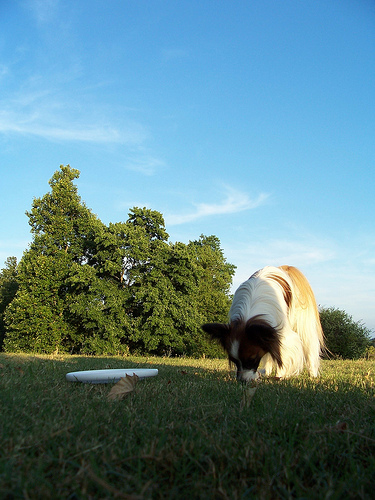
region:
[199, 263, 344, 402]
dog standing on the grass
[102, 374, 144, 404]
leaf on the ground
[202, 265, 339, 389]
dog with long hair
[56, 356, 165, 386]
Frisbee laying on the ground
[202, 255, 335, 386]
white and brown dog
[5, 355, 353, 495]
shadow on the ground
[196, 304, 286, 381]
head bent down to the ground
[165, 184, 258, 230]
thin white cloud in the sky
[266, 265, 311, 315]
light shining on the dog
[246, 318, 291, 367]
long brown hair on the ear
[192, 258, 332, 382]
this is a dog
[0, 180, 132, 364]
this is a tree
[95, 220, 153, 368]
this is a tree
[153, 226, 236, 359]
this is a tree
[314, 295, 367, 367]
this is a tree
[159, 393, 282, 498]
this is a patch of grass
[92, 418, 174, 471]
this is a patch of grass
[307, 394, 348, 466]
this is a patch of grass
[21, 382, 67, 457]
this is a patch of grass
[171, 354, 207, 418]
this is a patch of grass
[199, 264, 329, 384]
a white and brown dog sniffing the grass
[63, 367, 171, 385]
a frisbee in the grass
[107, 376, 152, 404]
a dead leaf on the grass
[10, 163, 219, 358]
a bunch of trees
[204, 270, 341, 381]
a long haired dog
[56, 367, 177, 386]
a white dog toy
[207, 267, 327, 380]
a dog staring at the ground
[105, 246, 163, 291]
the sky peaking through the trees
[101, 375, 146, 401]
a brown leaf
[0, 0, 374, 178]
a blue sky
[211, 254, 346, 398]
A small, furry dog in the field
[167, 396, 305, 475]
Grass growing by the dog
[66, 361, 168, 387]
A white frisbee lying in the field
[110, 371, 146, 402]
A dead leaf lying in the grass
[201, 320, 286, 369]
Brown fur on the dog's head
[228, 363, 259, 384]
The dog's nose is in the grass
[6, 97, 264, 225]
Wispy white clouds in the sky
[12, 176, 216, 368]
Green trees growing behind the dog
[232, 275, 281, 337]
A shadow on the dog's back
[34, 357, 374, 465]
A tree's shadow on the ground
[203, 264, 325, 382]
A dog sniffing in the grass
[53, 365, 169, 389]
A frisbe lying in the grass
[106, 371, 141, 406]
A brown leaf on the ground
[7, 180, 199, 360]
Pine trees growing in the distance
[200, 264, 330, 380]
Long haired chihuahua rooting in the grass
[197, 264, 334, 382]
A brown and white puppy sniffing the grass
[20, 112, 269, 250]
Sparse clouds floating above the trees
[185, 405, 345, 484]
Grass growing in a meadow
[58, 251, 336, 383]
Dog distracted from playing frisbe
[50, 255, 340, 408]
A dog playing frisbee in the yard